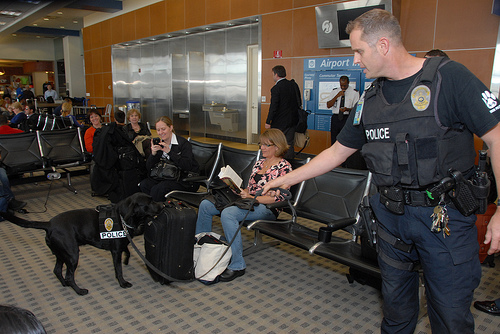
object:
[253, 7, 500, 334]
man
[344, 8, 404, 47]
hair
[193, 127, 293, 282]
woman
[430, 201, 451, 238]
keys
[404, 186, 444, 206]
belt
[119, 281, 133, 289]
paw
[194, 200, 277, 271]
jeans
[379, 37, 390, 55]
ear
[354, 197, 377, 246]
gun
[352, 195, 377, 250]
thigh holster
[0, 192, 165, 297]
dog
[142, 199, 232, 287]
baggage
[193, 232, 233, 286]
bag